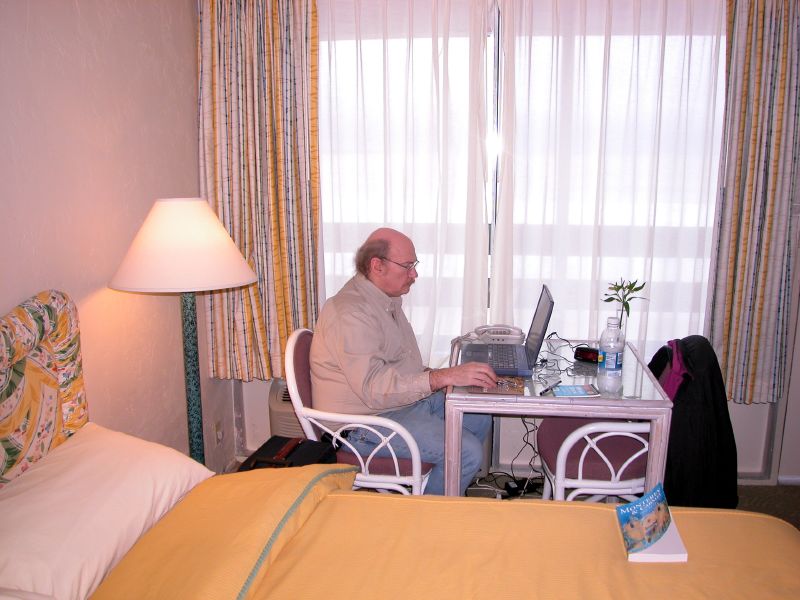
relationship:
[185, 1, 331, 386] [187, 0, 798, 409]
curtain panel on window